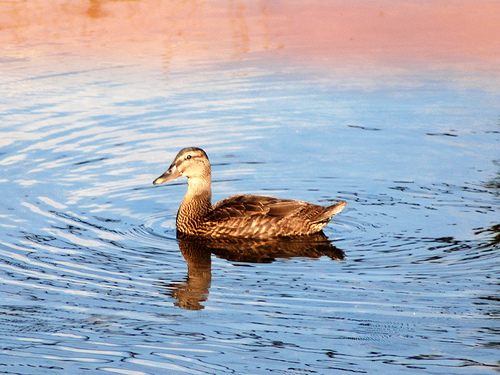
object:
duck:
[152, 146, 348, 243]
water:
[0, 1, 500, 375]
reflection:
[161, 233, 354, 310]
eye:
[186, 154, 192, 160]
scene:
[0, 1, 500, 373]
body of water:
[0, 41, 498, 373]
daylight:
[0, 0, 500, 251]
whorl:
[0, 115, 500, 375]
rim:
[184, 152, 193, 162]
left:
[0, 0, 260, 374]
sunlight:
[0, 49, 342, 375]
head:
[151, 141, 217, 190]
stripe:
[175, 154, 204, 166]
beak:
[152, 162, 183, 186]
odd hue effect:
[0, 0, 500, 117]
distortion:
[161, 232, 347, 312]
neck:
[179, 168, 213, 210]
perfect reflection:
[175, 241, 214, 270]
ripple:
[0, 57, 500, 375]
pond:
[0, 69, 500, 375]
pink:
[1, 0, 499, 77]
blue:
[0, 70, 500, 375]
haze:
[0, 46, 499, 106]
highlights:
[173, 140, 213, 181]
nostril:
[168, 169, 173, 173]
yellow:
[156, 179, 164, 184]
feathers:
[175, 193, 345, 238]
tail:
[321, 201, 348, 222]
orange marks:
[0, 0, 500, 96]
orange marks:
[7, 22, 100, 46]